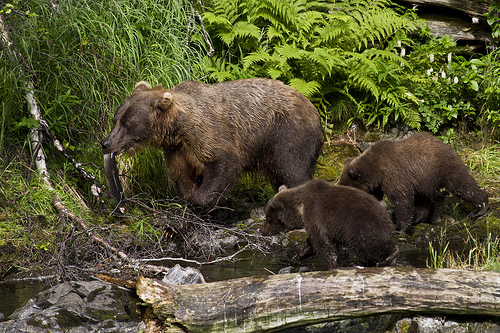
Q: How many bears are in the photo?
A: Three.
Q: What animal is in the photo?
A: Bear.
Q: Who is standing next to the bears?
A: No one.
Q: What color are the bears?
A: Brown.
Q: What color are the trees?
A: Green.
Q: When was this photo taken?
A: Daytime.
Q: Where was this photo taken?
A: In the woods.